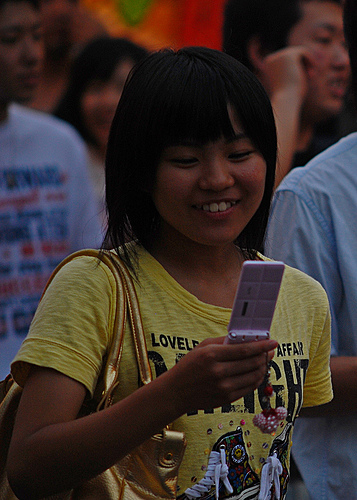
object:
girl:
[11, 44, 335, 499]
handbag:
[0, 248, 187, 499]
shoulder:
[61, 239, 156, 301]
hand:
[169, 336, 278, 411]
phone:
[223, 261, 285, 345]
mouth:
[189, 197, 243, 219]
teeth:
[196, 203, 236, 212]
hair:
[91, 45, 277, 287]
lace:
[180, 434, 240, 499]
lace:
[256, 424, 286, 500]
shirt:
[9, 239, 335, 500]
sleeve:
[298, 307, 334, 409]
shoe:
[175, 425, 262, 500]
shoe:
[257, 422, 291, 500]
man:
[225, 0, 351, 198]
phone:
[248, 20, 288, 59]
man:
[2, 1, 103, 377]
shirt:
[2, 102, 102, 380]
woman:
[53, 36, 152, 249]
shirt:
[90, 155, 132, 243]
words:
[275, 340, 307, 357]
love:
[151, 333, 187, 349]